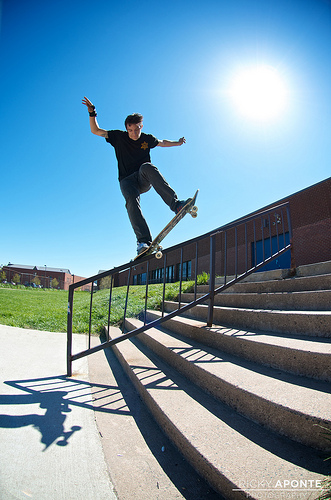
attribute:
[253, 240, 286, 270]
doors — blue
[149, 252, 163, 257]
wheel — white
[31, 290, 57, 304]
grass — green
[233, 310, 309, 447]
stairs — cement, concrete, grey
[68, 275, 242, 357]
railing — metal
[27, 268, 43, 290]
tree — green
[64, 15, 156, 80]
sky — blue